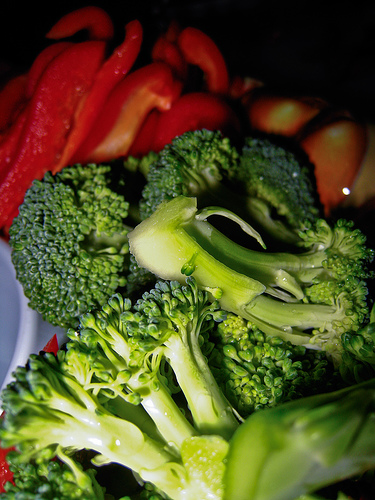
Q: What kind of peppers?
A: Red bell.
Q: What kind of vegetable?
A: Broccoli.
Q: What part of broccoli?
A: Stem.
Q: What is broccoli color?
A: Green.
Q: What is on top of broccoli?
A: More broccoli.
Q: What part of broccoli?
A: Crown.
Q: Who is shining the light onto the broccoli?
A: The person taking the photo.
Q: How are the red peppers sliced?
A: They were sliced into long pieces.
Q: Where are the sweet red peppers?
A: Behind the broccoli.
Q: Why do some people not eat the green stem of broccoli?
A: Too stringy.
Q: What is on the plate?
A: Vegetables.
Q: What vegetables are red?
A: Peppers.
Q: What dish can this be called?
A: Raw crudite.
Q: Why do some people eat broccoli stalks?
A: They like the texture.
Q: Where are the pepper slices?
A: On a plate.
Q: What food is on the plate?
A: Vegetables.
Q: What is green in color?
A: The broccoli.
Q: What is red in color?
A: Sliced peppers.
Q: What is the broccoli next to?
A: The peppers.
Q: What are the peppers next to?
A: The broccoli.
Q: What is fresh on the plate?
A: The vegetables.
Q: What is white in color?
A: The plate.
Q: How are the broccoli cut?
A: Into florets.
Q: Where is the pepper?
A: Next to the broccoli.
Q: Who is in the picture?
A: Nobody.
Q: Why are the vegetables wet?
A: They were recently washed.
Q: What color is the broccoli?
A: Green.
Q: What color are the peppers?
A: Red.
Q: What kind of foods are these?
A: Vegetables.